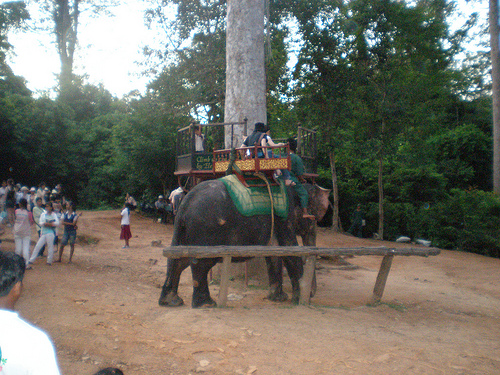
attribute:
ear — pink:
[313, 182, 329, 227]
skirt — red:
[118, 224, 132, 239]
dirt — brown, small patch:
[296, 338, 380, 373]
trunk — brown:
[225, 0, 267, 144]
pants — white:
[35, 226, 55, 266]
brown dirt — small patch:
[0, 202, 498, 374]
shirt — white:
[2, 308, 60, 374]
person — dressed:
[286, 137, 314, 219]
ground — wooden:
[283, 308, 360, 360]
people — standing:
[4, 177, 170, 329]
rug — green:
[224, 173, 295, 220]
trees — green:
[0, 3, 500, 245]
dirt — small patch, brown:
[2, 205, 499, 373]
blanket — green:
[213, 163, 294, 218]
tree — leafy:
[264, 0, 498, 251]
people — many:
[4, 181, 79, 271]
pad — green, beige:
[222, 173, 290, 218]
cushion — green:
[217, 170, 301, 220]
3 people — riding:
[153, 87, 389, 202]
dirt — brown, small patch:
[185, 306, 387, 348]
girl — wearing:
[49, 205, 86, 266]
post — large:
[158, 241, 443, 306]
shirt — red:
[96, 193, 161, 277]